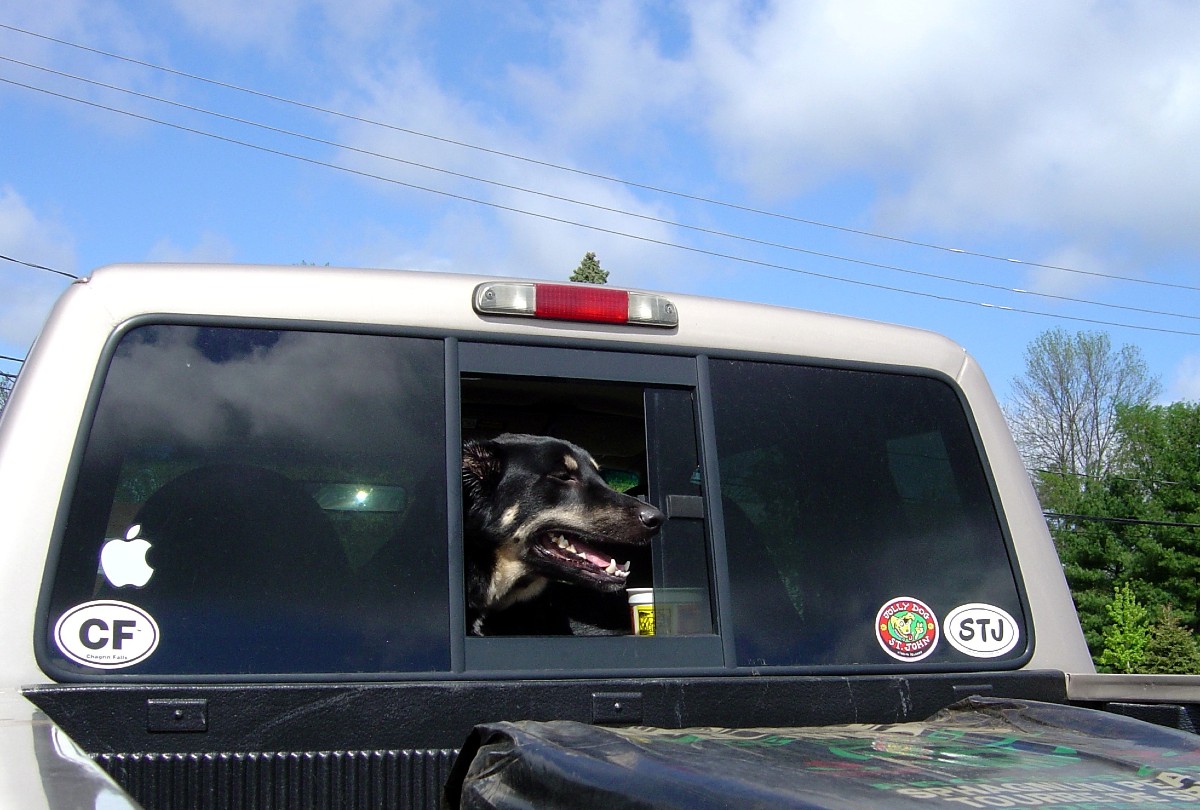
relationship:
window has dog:
[224, 280, 822, 568] [456, 434, 686, 608]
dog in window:
[456, 434, 686, 608] [224, 280, 822, 568]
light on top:
[471, 215, 806, 371] [157, 251, 927, 349]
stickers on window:
[717, 514, 1038, 670] [224, 280, 822, 568]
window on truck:
[224, 280, 822, 568] [257, 253, 1105, 612]